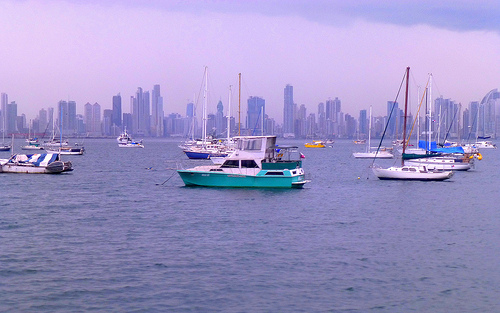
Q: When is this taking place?
A: Daytime.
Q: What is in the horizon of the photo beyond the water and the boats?
A: Buildings.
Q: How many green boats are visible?
A: One.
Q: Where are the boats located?
A: Water.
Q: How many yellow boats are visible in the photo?
A: One.